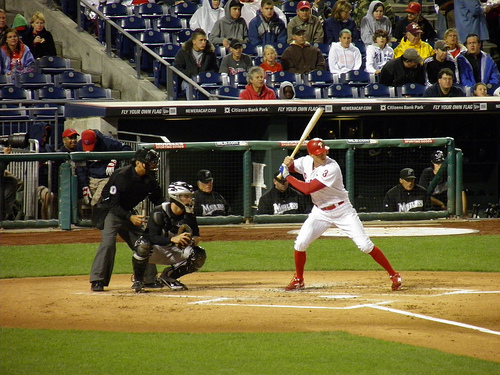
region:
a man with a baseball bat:
[235, 85, 429, 322]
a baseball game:
[51, 84, 458, 323]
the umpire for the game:
[68, 132, 169, 303]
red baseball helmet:
[290, 120, 347, 172]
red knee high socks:
[265, 224, 429, 304]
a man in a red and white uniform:
[266, 108, 423, 310]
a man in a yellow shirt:
[390, 17, 447, 72]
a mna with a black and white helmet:
[143, 159, 228, 299]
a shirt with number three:
[293, 149, 358, 209]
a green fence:
[17, 127, 482, 232]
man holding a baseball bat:
[278, 106, 402, 297]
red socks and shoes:
[286, 248, 308, 290]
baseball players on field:
[4, 138, 492, 366]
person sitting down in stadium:
[239, 64, 275, 99]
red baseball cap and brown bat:
[274, 103, 332, 194]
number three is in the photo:
[316, 168, 328, 178]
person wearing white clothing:
[328, 29, 364, 77]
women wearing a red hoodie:
[241, 68, 275, 101]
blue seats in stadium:
[1, 64, 113, 127]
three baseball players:
[85, 134, 411, 310]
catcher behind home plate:
[132, 182, 207, 290]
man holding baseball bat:
[273, 110, 403, 293]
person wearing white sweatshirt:
[331, 31, 360, 76]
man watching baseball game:
[458, 36, 497, 92]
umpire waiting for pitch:
[85, 143, 167, 291]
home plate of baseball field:
[178, 276, 478, 314]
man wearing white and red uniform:
[281, 136, 406, 297]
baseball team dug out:
[162, 136, 497, 220]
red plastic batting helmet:
[304, 137, 332, 157]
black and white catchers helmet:
[167, 178, 197, 217]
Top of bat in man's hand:
[289, 100, 326, 142]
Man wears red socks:
[285, 246, 312, 278]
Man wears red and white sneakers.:
[271, 275, 318, 296]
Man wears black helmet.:
[125, 141, 167, 176]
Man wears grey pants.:
[90, 212, 137, 307]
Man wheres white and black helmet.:
[166, 180, 203, 209]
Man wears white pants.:
[298, 206, 370, 251]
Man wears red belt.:
[312, 195, 348, 215]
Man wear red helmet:
[302, 131, 334, 161]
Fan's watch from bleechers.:
[148, 45, 497, 99]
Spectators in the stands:
[178, 0, 496, 95]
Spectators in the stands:
[1, 7, 86, 100]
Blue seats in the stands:
[30, 60, 100, 106]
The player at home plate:
[279, 107, 416, 309]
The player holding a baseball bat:
[261, 95, 406, 308]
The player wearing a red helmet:
[272, 100, 402, 297]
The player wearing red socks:
[282, 98, 414, 300]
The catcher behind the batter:
[137, 180, 214, 297]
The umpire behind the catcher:
[83, 137, 165, 296]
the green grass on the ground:
[4, 232, 499, 372]